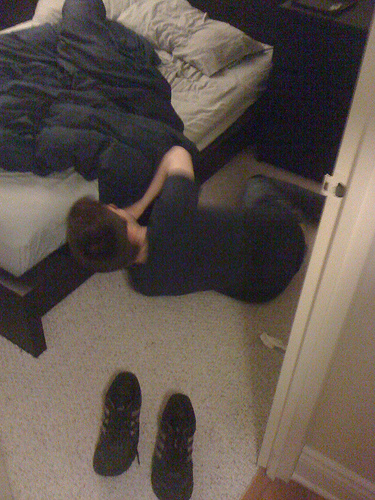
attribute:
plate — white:
[324, 176, 344, 209]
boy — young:
[48, 164, 334, 303]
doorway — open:
[3, 2, 374, 494]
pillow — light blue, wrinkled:
[116, 0, 268, 78]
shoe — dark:
[147, 391, 213, 495]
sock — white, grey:
[253, 329, 291, 357]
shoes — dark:
[61, 367, 227, 494]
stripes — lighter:
[139, 422, 175, 463]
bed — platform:
[2, 32, 285, 354]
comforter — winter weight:
[1, 1, 205, 211]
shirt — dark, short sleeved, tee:
[144, 185, 280, 282]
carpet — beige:
[1, 289, 263, 499]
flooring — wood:
[131, 314, 221, 376]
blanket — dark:
[0, 1, 201, 226]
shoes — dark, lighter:
[91, 369, 196, 498]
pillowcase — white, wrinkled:
[185, 15, 261, 67]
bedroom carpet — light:
[216, 166, 257, 196]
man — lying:
[67, 143, 304, 304]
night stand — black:
[259, 17, 336, 193]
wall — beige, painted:
[304, 233, 372, 486]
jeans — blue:
[229, 172, 324, 221]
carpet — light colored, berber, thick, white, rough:
[0, 143, 322, 499]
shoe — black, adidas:
[147, 389, 202, 497]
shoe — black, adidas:
[85, 366, 146, 480]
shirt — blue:
[125, 177, 296, 314]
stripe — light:
[183, 434, 192, 458]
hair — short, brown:
[63, 195, 140, 273]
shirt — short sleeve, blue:
[125, 173, 307, 305]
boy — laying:
[67, 146, 313, 332]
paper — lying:
[258, 330, 283, 359]